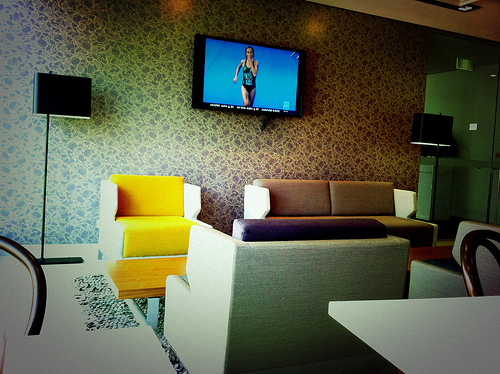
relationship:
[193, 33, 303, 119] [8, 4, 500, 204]
tv on wall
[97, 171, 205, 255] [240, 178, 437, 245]
chair near loveseat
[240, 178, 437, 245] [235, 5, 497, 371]
loveseat to left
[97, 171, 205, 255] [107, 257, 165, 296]
chair near table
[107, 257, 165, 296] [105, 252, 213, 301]
table for coffee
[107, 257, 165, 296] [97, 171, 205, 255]
table in front of chair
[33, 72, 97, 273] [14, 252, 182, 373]
lamp on floor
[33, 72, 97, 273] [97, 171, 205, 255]
lamp near chair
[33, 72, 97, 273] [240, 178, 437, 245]
lamp near loveseat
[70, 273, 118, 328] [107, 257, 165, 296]
rug under table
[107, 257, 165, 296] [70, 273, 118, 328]
table on rug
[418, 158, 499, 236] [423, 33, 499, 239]
boxes in corner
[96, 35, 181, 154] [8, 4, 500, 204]
spots on wall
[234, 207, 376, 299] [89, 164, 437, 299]
table in middle of furniture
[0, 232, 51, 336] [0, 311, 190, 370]
chair behind white table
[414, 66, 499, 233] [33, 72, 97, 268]
green armoire next to lamp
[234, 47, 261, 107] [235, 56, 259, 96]
runner in swimsuit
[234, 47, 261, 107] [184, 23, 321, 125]
runner on tv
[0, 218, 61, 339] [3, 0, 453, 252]
chair against wall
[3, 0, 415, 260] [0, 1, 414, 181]
wallpaper looks like scales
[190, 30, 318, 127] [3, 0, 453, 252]
television mounted on wall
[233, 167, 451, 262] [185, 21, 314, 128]
loveseat beneath television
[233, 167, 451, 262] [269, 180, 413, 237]
loveseat has fabric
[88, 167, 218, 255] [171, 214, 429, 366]
chair has chair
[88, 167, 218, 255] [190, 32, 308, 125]
chair beneath television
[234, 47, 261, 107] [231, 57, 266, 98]
runner wearing swimsuit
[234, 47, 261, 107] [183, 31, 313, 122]
runner on television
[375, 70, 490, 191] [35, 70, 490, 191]
cabinets on wall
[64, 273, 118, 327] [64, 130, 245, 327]
rug to left of chair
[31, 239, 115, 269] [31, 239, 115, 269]
base on floor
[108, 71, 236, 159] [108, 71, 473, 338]
wallpaper above furniture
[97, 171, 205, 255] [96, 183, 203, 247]
chair of chair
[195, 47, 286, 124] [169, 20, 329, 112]
runner on screen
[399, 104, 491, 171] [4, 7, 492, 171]
lamp on right side of room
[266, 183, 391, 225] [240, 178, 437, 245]
cushions on back of loveseat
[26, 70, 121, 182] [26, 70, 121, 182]
box on wall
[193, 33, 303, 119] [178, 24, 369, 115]
tv on wall